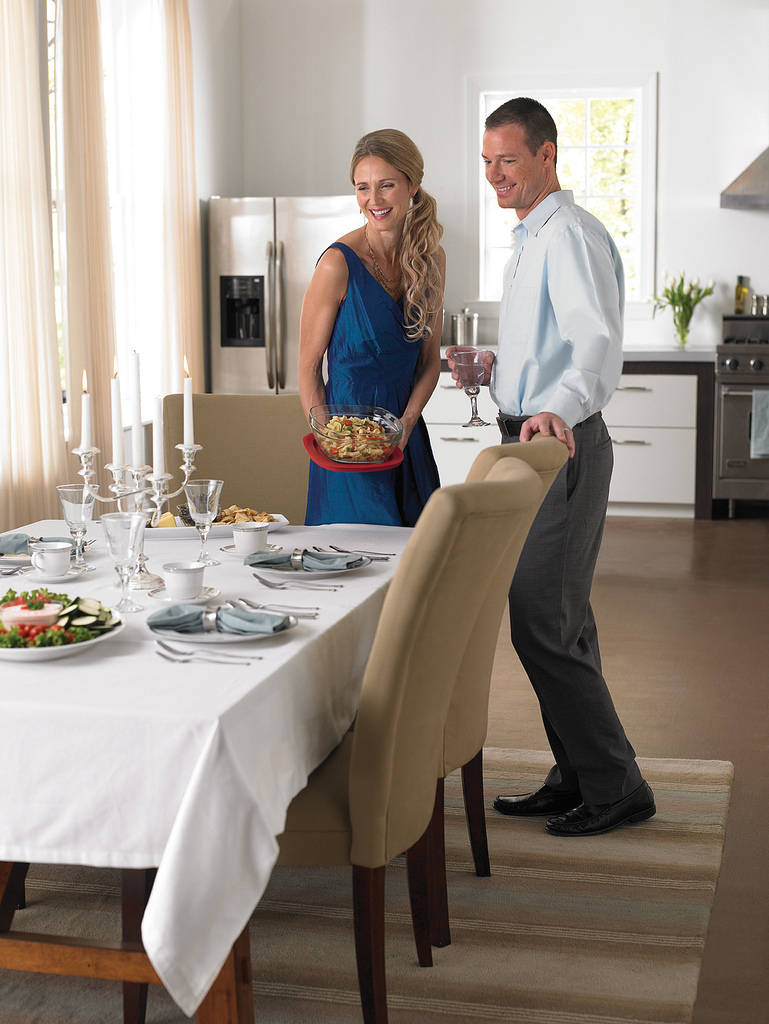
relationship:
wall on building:
[185, 4, 767, 363] [11, 15, 766, 1021]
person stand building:
[472, 88, 666, 851] [0, 0, 769, 1024]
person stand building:
[294, 116, 457, 543] [0, 0, 769, 1024]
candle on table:
[172, 352, 206, 454] [7, 506, 448, 1019]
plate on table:
[247, 539, 376, 586] [2, 511, 453, 970]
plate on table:
[8, 559, 95, 714] [7, 506, 448, 1019]